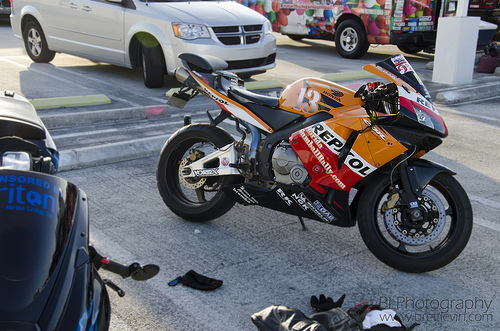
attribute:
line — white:
[4, 52, 176, 126]